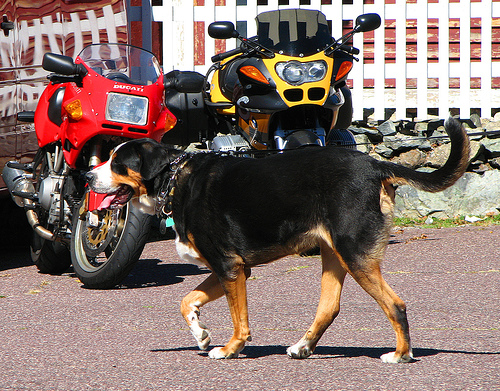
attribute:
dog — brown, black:
[74, 121, 473, 363]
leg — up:
[179, 260, 226, 352]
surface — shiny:
[1, 39, 205, 279]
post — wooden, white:
[394, 1, 410, 119]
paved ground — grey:
[3, 222, 498, 387]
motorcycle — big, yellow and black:
[175, 10, 383, 230]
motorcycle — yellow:
[192, 0, 389, 171]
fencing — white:
[128, 1, 498, 119]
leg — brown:
[281, 243, 353, 356]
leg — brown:
[340, 247, 421, 367]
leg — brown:
[209, 264, 255, 365]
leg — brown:
[179, 262, 249, 351]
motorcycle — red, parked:
[0, 37, 216, 288]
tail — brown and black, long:
[375, 117, 472, 192]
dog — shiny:
[55, 112, 477, 369]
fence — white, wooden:
[148, 0, 498, 120]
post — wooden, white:
[372, 0, 384, 118]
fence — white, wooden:
[160, 1, 198, 92]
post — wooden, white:
[146, 9, 231, 93]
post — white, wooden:
[453, 0, 477, 120]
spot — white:
[92, 166, 115, 194]